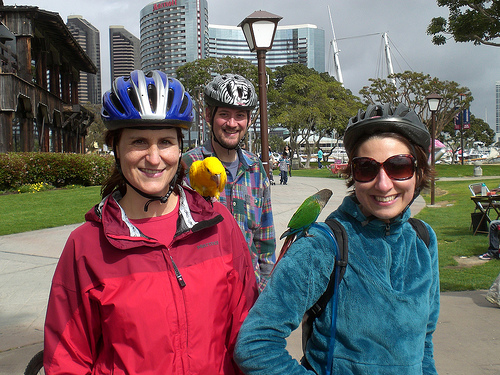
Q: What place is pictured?
A: It is a park.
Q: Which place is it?
A: It is a park.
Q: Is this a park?
A: Yes, it is a park.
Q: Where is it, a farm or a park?
A: It is a park.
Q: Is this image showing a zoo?
A: No, the picture is showing a park.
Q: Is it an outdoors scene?
A: Yes, it is outdoors.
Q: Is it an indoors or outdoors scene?
A: It is outdoors.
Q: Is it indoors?
A: No, it is outdoors.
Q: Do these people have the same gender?
A: No, they are both male and female.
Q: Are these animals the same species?
A: Yes, all the animals are birds.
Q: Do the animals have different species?
A: No, all the animals are birds.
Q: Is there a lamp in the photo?
A: Yes, there is a lamp.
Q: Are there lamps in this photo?
A: Yes, there is a lamp.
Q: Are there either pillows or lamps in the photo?
A: Yes, there is a lamp.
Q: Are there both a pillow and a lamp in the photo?
A: No, there is a lamp but no pillows.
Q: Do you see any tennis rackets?
A: No, there are no tennis rackets.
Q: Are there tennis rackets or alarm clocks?
A: No, there are no tennis rackets or alarm clocks.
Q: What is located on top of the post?
A: The lamp is on top of the post.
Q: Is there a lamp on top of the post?
A: Yes, there is a lamp on top of the post.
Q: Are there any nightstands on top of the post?
A: No, there is a lamp on top of the post.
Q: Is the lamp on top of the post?
A: Yes, the lamp is on top of the post.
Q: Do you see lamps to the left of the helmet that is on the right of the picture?
A: Yes, there is a lamp to the left of the helmet.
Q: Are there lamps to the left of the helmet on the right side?
A: Yes, there is a lamp to the left of the helmet.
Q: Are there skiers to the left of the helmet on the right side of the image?
A: No, there is a lamp to the left of the helmet.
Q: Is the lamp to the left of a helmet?
A: Yes, the lamp is to the left of a helmet.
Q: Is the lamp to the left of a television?
A: No, the lamp is to the left of a helmet.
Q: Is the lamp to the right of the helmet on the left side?
A: Yes, the lamp is to the right of the helmet.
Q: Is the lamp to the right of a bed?
A: No, the lamp is to the right of the helmet.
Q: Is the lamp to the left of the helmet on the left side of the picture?
A: No, the lamp is to the right of the helmet.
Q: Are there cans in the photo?
A: No, there are no cans.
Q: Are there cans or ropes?
A: No, there are no cans or ropes.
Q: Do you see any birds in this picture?
A: Yes, there is a bird.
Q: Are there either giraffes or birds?
A: Yes, there is a bird.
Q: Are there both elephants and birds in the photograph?
A: No, there is a bird but no elephants.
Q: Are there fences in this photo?
A: No, there are no fences.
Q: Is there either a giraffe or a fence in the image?
A: No, there are no fences or giraffes.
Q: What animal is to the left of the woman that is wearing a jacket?
A: The animal is a bird.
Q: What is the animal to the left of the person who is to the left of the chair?
A: The animal is a bird.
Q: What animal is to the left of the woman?
A: The animal is a bird.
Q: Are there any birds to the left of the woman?
A: Yes, there is a bird to the left of the woman.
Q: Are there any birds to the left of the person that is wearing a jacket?
A: Yes, there is a bird to the left of the woman.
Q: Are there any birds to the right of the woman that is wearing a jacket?
A: No, the bird is to the left of the woman.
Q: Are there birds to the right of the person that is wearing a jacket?
A: No, the bird is to the left of the woman.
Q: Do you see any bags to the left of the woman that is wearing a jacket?
A: No, there is a bird to the left of the woman.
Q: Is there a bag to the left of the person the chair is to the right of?
A: No, there is a bird to the left of the woman.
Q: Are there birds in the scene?
A: Yes, there is a bird.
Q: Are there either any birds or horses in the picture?
A: Yes, there is a bird.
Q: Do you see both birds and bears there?
A: No, there is a bird but no bears.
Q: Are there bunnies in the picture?
A: No, there are no bunnies.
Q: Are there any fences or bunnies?
A: No, there are no bunnies or fences.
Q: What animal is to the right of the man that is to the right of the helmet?
A: The animal is a bird.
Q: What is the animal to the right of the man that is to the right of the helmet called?
A: The animal is a bird.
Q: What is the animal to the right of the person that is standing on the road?
A: The animal is a bird.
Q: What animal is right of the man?
A: The animal is a bird.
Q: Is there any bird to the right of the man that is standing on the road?
A: Yes, there is a bird to the right of the man.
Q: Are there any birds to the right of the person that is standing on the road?
A: Yes, there is a bird to the right of the man.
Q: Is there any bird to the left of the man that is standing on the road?
A: No, the bird is to the right of the man.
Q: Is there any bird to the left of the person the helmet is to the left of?
A: No, the bird is to the right of the man.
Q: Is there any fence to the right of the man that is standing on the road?
A: No, there is a bird to the right of the man.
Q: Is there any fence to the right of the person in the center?
A: No, there is a bird to the right of the man.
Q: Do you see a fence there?
A: No, there are no fences.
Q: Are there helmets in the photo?
A: Yes, there is a helmet.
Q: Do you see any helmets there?
A: Yes, there is a helmet.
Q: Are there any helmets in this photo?
A: Yes, there is a helmet.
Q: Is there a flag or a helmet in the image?
A: Yes, there is a helmet.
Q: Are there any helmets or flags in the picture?
A: Yes, there is a helmet.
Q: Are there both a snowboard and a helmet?
A: No, there is a helmet but no snowboards.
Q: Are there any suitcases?
A: No, there are no suitcases.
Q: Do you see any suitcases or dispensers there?
A: No, there are no suitcases or dispensers.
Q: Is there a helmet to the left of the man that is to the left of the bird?
A: Yes, there is a helmet to the left of the man.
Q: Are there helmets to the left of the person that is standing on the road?
A: Yes, there is a helmet to the left of the man.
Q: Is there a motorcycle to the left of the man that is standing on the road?
A: No, there is a helmet to the left of the man.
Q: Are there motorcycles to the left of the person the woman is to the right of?
A: No, there is a helmet to the left of the man.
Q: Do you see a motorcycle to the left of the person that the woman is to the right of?
A: No, there is a helmet to the left of the man.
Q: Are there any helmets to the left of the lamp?
A: Yes, there is a helmet to the left of the lamp.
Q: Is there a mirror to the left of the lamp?
A: No, there is a helmet to the left of the lamp.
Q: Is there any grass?
A: Yes, there is grass.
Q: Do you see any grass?
A: Yes, there is grass.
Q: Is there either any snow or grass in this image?
A: Yes, there is grass.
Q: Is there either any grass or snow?
A: Yes, there is grass.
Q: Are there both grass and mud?
A: No, there is grass but no mud.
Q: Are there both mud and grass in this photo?
A: No, there is grass but no mud.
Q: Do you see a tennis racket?
A: No, there are no rackets.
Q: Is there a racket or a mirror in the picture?
A: No, there are no rackets or mirrors.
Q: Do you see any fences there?
A: No, there are no fences.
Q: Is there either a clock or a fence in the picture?
A: No, there are no fences or clocks.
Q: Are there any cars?
A: No, there are no cars.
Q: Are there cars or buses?
A: No, there are no cars or buses.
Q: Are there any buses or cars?
A: No, there are no cars or buses.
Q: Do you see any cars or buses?
A: No, there are no cars or buses.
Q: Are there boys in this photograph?
A: No, there are no boys.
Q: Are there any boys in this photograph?
A: No, there are no boys.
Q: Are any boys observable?
A: No, there are no boys.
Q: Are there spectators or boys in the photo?
A: No, there are no boys or spectators.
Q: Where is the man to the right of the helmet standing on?
A: The man is standing on the road.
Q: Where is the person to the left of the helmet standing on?
A: The man is standing on the road.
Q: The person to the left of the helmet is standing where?
A: The man is standing on the road.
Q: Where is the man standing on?
A: The man is standing on the road.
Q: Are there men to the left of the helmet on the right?
A: Yes, there is a man to the left of the helmet.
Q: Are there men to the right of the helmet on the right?
A: No, the man is to the left of the helmet.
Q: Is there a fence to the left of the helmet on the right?
A: No, there is a man to the left of the helmet.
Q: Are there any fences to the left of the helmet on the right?
A: No, there is a man to the left of the helmet.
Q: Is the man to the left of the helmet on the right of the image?
A: Yes, the man is to the left of the helmet.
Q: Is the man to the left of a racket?
A: No, the man is to the left of the helmet.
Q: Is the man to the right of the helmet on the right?
A: No, the man is to the left of the helmet.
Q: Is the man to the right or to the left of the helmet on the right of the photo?
A: The man is to the left of the helmet.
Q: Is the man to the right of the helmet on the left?
A: Yes, the man is to the right of the helmet.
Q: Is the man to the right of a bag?
A: No, the man is to the right of the helmet.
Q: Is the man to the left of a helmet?
A: No, the man is to the right of a helmet.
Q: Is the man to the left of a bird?
A: Yes, the man is to the left of a bird.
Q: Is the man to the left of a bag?
A: No, the man is to the left of a bird.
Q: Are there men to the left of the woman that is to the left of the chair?
A: Yes, there is a man to the left of the woman.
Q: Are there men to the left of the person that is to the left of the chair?
A: Yes, there is a man to the left of the woman.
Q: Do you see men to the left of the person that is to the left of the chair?
A: Yes, there is a man to the left of the woman.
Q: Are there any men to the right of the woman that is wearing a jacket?
A: No, the man is to the left of the woman.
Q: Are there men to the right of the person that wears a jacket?
A: No, the man is to the left of the woman.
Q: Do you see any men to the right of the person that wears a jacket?
A: No, the man is to the left of the woman.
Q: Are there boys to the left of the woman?
A: No, there is a man to the left of the woman.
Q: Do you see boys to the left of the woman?
A: No, there is a man to the left of the woman.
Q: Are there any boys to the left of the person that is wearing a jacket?
A: No, there is a man to the left of the woman.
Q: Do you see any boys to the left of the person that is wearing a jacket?
A: No, there is a man to the left of the woman.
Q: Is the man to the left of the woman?
A: Yes, the man is to the left of the woman.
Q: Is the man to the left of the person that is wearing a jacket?
A: Yes, the man is to the left of the woman.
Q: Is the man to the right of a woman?
A: No, the man is to the left of a woman.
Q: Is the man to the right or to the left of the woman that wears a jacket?
A: The man is to the left of the woman.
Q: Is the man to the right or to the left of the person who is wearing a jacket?
A: The man is to the left of the woman.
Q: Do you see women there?
A: Yes, there is a woman.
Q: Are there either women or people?
A: Yes, there is a woman.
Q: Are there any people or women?
A: Yes, there is a woman.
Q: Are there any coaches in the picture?
A: No, there are no coaches.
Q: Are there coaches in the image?
A: No, there are no coaches.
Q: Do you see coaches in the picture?
A: No, there are no coaches.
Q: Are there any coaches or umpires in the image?
A: No, there are no coaches or umpires.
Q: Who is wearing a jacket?
A: The woman is wearing a jacket.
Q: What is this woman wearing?
A: The woman is wearing a jacket.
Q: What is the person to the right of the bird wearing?
A: The woman is wearing a jacket.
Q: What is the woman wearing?
A: The woman is wearing a jacket.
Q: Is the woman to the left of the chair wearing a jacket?
A: Yes, the woman is wearing a jacket.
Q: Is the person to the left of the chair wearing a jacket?
A: Yes, the woman is wearing a jacket.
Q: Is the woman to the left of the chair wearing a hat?
A: No, the woman is wearing a jacket.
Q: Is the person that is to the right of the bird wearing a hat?
A: No, the woman is wearing a jacket.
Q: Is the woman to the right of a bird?
A: Yes, the woman is to the right of a bird.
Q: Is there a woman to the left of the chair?
A: Yes, there is a woman to the left of the chair.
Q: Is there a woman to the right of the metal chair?
A: No, the woman is to the left of the chair.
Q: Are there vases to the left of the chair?
A: No, there is a woman to the left of the chair.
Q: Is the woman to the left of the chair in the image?
A: Yes, the woman is to the left of the chair.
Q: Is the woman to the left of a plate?
A: No, the woman is to the left of the chair.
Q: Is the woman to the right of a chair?
A: No, the woman is to the left of a chair.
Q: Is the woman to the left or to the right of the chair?
A: The woman is to the left of the chair.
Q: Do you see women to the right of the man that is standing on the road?
A: Yes, there is a woman to the right of the man.